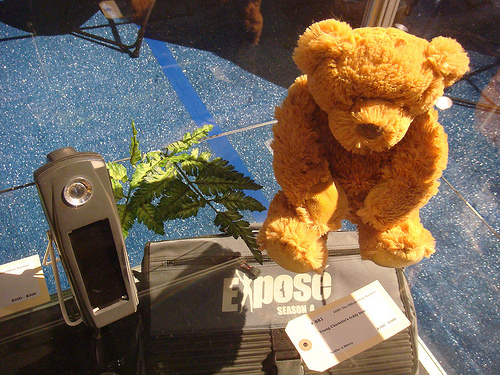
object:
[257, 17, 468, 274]
teddy bear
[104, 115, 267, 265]
leaves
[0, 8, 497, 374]
table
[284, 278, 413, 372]
tag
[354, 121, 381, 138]
nose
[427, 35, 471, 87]
ear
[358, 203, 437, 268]
leg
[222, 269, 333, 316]
word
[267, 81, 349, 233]
arm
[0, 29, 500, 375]
floor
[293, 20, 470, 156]
face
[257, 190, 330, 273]
leg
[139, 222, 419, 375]
brief case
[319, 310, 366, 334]
words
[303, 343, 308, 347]
hole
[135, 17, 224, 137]
blue tape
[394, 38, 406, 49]
heart button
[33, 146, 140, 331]
electronic item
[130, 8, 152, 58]
leg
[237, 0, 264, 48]
reflection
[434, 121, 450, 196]
light